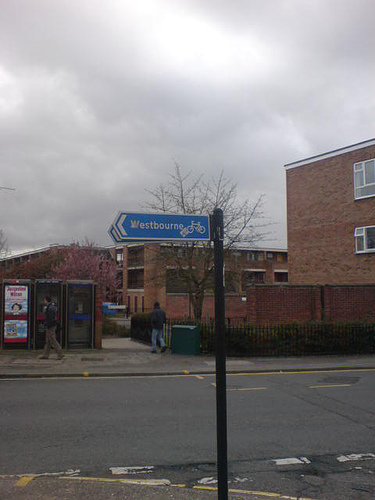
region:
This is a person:
[142, 296, 170, 363]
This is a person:
[39, 292, 77, 381]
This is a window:
[349, 221, 373, 261]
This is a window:
[350, 156, 373, 211]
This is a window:
[243, 247, 260, 261]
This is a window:
[264, 250, 279, 262]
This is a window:
[238, 264, 265, 287]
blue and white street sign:
[103, 207, 214, 248]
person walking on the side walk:
[145, 296, 170, 356]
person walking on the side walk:
[37, 293, 66, 365]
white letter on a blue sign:
[137, 219, 146, 229]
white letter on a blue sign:
[142, 219, 149, 229]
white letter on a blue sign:
[148, 218, 153, 230]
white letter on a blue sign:
[151, 218, 160, 229]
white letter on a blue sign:
[158, 220, 163, 231]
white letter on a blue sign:
[161, 219, 170, 229]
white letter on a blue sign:
[170, 221, 181, 232]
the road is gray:
[8, 375, 373, 496]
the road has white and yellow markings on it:
[7, 368, 370, 496]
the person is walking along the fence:
[146, 297, 211, 357]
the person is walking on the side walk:
[30, 295, 90, 376]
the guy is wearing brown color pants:
[38, 296, 65, 360]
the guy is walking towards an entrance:
[100, 277, 166, 355]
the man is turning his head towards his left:
[37, 292, 65, 358]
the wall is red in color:
[158, 285, 373, 326]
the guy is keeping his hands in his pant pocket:
[38, 296, 64, 361]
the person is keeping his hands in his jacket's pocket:
[148, 299, 167, 352]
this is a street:
[19, 93, 327, 429]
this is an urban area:
[25, 135, 348, 459]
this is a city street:
[42, 142, 328, 395]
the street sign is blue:
[101, 189, 222, 276]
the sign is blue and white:
[88, 168, 263, 290]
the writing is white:
[124, 194, 191, 232]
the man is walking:
[106, 268, 183, 339]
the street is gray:
[69, 391, 206, 471]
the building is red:
[271, 197, 342, 289]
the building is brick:
[295, 174, 352, 258]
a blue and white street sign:
[107, 208, 212, 242]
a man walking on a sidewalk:
[37, 294, 66, 360]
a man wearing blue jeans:
[150, 323, 167, 351]